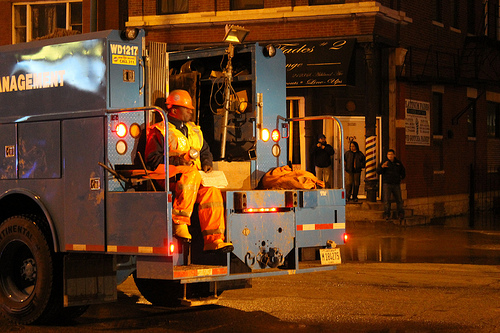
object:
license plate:
[320, 248, 342, 266]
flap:
[63, 253, 117, 308]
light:
[115, 123, 127, 138]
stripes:
[364, 135, 377, 181]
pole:
[363, 43, 379, 202]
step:
[176, 274, 221, 308]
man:
[144, 89, 234, 257]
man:
[344, 140, 366, 202]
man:
[310, 133, 336, 189]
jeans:
[382, 181, 405, 217]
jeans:
[345, 171, 362, 199]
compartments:
[57, 117, 108, 251]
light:
[271, 128, 281, 142]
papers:
[198, 170, 229, 189]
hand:
[203, 164, 213, 174]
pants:
[154, 163, 225, 245]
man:
[374, 150, 407, 222]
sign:
[276, 37, 357, 89]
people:
[308, 134, 406, 221]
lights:
[260, 128, 281, 143]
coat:
[341, 149, 366, 173]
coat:
[376, 157, 406, 184]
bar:
[105, 101, 185, 192]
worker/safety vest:
[143, 120, 206, 171]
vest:
[149, 119, 204, 170]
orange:
[167, 132, 182, 146]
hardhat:
[165, 89, 196, 110]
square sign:
[403, 98, 432, 146]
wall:
[405, 75, 471, 197]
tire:
[0, 212, 89, 327]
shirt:
[144, 114, 214, 171]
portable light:
[219, 23, 250, 163]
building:
[0, 1, 500, 227]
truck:
[0, 28, 350, 327]